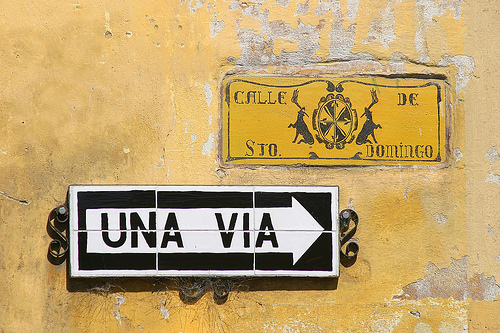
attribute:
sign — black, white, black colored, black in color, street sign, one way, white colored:
[65, 184, 339, 281]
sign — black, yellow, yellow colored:
[223, 69, 452, 163]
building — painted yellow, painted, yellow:
[2, 4, 500, 331]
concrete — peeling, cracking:
[399, 255, 496, 308]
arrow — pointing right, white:
[88, 196, 328, 264]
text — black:
[234, 83, 289, 108]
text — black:
[240, 134, 282, 160]